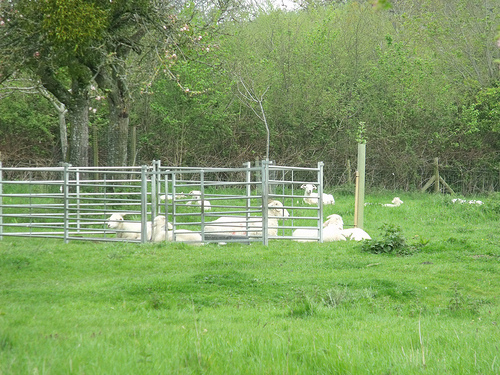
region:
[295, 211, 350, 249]
this is a sheep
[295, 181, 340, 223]
this is a sheep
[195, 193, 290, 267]
this is a sheep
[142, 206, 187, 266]
this is a sheep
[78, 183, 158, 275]
this is a sheep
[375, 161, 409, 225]
this is a sheep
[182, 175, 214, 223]
this is a sheep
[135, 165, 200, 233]
this is a sheep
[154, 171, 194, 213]
this is a sheep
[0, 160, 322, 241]
Sheep pen made of metal bars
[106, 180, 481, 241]
Some white sheep inside and outside the pen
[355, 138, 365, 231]
A green metal pole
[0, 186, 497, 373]
Grassy field where the sheep are sitting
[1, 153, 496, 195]
Fence of hedge bush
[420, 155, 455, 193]
Supporting poles of the fence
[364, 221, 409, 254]
A small bush within the grassy field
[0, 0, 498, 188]
A thicket of trees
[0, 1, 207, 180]
Two big trees with some pinkish flowers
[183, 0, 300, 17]
A small part of sky visible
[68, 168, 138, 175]
silver wooden fence pole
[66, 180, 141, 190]
silver wooden fence pole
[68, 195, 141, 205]
silver wooden fence pole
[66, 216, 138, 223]
silver wooden fence pole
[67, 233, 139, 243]
silver wooden fence pole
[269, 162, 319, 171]
silver wooden fence pole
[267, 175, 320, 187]
silver wooden fence pole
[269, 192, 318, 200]
silver wooden fence pole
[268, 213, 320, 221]
silver wooden fence pole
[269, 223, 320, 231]
silver wooden fence pole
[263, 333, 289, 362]
[[art pf a graas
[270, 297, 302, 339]
part of a grass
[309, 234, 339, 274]
part of a ground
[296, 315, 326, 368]
part of a grass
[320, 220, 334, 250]
part fo a sheep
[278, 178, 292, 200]
part 0pf a fence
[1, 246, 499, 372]
Lush, green grass in an enclosure.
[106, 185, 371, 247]
Lambs laying in the green grass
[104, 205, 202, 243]
Sheep behind a metal gate.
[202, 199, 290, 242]
A sheep behind a metal gate.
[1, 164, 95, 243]
Metal gate of a sheep enclosure.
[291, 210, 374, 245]
Goats laying in the grass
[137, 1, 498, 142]
Trees and empty branches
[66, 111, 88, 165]
Trunk of a tree.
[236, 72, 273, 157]
A small tree without any leaves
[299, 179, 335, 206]
A goat laying in grass.